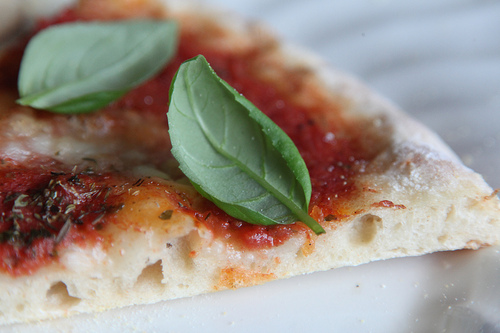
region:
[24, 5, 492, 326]
White, round plate with ridges on its edges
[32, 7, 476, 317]
A white thin crust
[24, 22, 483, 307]
The pizza crust has air bubbles in it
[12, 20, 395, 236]
There is red sauce with black seasoning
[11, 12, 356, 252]
Small green leaves are on the sauce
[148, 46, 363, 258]
The edges of the leaf are curved inward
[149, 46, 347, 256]
The leaf is small and green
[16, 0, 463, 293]
The pizza is on top of the plate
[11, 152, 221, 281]
Black pepper is mixed in with the red sauce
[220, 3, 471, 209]
The crust has white flour on top of it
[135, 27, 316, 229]
the leaf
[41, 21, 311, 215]
two basil leaves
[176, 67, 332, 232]
a basil leaf turned upside down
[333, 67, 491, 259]
pizza crust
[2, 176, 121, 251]
dried herbs on a pizza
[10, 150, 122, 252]
tomato sauce with herbs on a pizza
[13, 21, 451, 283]
a slice of pizza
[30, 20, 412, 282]
a slice of pizza with basil leaves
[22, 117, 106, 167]
melted cheese on a pizza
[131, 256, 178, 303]
pocket of air on pizza crust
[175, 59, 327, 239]
a green basil leaf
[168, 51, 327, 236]
green basil leaf on slice of pizza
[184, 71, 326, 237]
center stem of basil lea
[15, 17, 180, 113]
basil leaf next to green basil leaf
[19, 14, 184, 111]
basil leaf is fresh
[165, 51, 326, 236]
basil leaf is upside down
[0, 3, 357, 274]
tomato sauce on pizza crust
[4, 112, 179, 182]
cheese next to basil leaf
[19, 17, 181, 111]
basil leaf in front of basil leaf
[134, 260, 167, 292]
air pockets in pizza crust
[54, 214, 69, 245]
fennel seeds on pizza crust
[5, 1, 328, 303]
close-up of a slice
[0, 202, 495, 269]
a line of crust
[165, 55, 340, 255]
basil leaf, upside down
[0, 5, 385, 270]
two basil leaves on a slice of pizza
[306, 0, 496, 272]
slice of pie on a silver surface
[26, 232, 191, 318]
air holes in cooked dough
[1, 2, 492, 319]
appetizing slice of pizza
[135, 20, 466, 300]
basil pizza with tomato sauce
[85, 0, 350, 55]
out of focus portion of a slice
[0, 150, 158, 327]
herbs cooked into the sauce